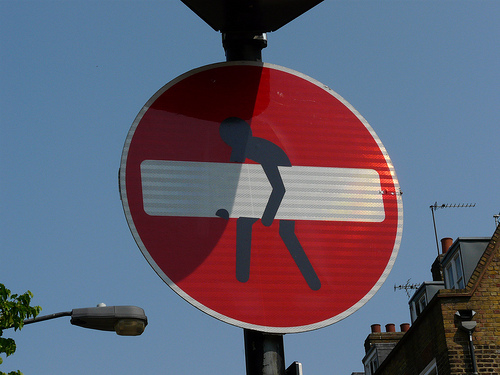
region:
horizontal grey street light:
[52, 291, 162, 343]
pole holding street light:
[10, 305, 77, 333]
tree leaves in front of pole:
[1, 269, 45, 363]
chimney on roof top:
[351, 315, 414, 355]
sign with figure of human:
[112, 45, 411, 339]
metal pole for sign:
[228, 330, 318, 370]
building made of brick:
[418, 250, 495, 369]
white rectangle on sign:
[133, 155, 388, 228]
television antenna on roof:
[424, 194, 481, 216]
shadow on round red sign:
[112, 52, 272, 284]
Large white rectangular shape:
[137, 151, 387, 228]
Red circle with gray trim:
[118, 61, 403, 336]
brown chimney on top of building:
[441, 237, 453, 254]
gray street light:
[70, 299, 150, 337]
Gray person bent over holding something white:
[216, 114, 326, 291]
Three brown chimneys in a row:
[371, 321, 415, 336]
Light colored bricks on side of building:
[475, 278, 498, 325]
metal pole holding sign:
[240, 331, 287, 374]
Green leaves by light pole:
[0, 288, 37, 366]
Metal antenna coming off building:
[392, 276, 419, 298]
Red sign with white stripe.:
[67, 61, 435, 332]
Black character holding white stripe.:
[175, 93, 362, 320]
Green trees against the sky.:
[5, 285, 58, 348]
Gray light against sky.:
[45, 290, 169, 356]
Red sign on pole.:
[89, 48, 494, 300]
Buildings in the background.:
[417, 167, 494, 327]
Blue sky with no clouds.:
[362, 30, 498, 125]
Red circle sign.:
[77, 54, 485, 340]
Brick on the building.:
[442, 300, 494, 342]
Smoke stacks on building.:
[422, 199, 481, 271]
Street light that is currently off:
[12, 297, 150, 349]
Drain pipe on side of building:
[452, 304, 490, 374]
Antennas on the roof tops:
[389, 194, 479, 295]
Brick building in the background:
[357, 211, 498, 374]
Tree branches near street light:
[0, 279, 40, 373]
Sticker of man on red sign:
[212, 114, 325, 293]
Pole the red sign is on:
[219, 30, 292, 372]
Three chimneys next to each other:
[365, 319, 413, 334]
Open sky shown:
[0, 0, 497, 374]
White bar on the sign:
[137, 153, 389, 227]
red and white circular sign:
[120, 47, 417, 331]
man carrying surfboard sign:
[117, 80, 442, 335]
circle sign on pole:
[106, 67, 425, 337]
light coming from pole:
[45, 300, 166, 355]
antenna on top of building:
[411, 175, 491, 296]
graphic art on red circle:
[201, 110, 336, 301]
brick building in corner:
[435, 278, 495, 369]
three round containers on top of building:
[360, 316, 408, 331]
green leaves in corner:
[3, 260, 33, 357]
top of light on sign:
[182, 0, 283, 66]